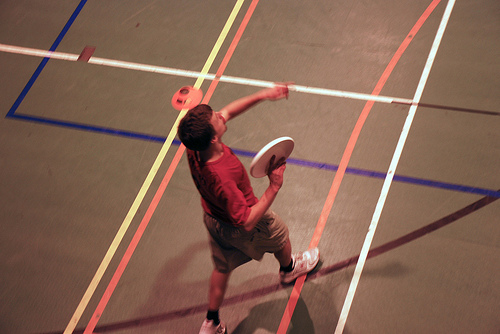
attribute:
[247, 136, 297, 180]
frisbee — white, sideways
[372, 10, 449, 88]
lines — multi-colored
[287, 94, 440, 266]
lines — multi-colored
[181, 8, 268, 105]
lines — multi-colored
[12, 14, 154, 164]
lines — multi-colored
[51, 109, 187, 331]
lines — multi-colored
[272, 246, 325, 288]
shoes — white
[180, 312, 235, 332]
shoes — white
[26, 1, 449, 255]
line — blue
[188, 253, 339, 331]
socks — ankle length, black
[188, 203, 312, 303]
shorts — light brown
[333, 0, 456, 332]
line — white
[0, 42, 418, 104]
line — white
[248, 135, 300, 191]
frisbee — white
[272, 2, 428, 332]
line — red, long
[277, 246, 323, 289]
shoe — white, tennis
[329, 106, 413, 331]
line — yellow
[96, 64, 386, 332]
man — playing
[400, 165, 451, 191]
line — dark purple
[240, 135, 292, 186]
frisbee — white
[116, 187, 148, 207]
line — light yellow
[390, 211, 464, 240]
line — black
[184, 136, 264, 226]
shirt — red